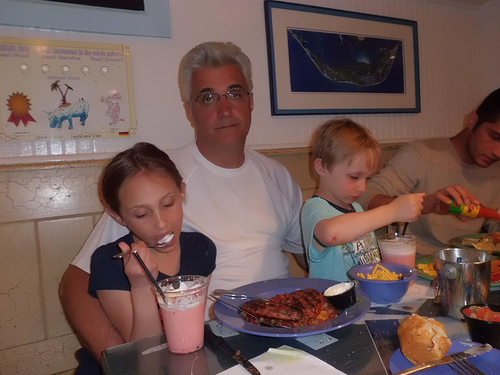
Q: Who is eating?
A: The girl.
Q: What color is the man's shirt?
A: White.